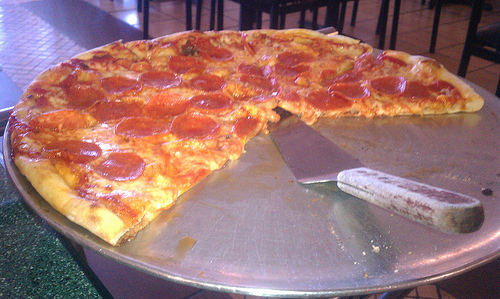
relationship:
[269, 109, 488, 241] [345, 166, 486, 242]
spatula with wooden handle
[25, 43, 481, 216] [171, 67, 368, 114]
pizza has pepperonis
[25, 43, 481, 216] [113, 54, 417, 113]
pizza covered with cheese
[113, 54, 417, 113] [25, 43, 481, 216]
cheese on pizza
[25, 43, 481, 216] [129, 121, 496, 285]
pizza on servingtray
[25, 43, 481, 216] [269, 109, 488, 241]
pizza with spatula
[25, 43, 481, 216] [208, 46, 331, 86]
pizza has redtoppings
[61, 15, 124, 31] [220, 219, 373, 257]
shadow on surface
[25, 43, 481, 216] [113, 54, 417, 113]
pizza made of cheese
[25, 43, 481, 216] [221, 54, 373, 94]
pizza has pepperoni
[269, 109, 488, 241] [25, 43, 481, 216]
spatula serves pizza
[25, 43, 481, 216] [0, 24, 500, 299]
pizza on pizzatray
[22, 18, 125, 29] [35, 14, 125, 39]
floor has tiles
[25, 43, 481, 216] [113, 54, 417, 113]
pizza has cheese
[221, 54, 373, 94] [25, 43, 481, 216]
pepperoni on pizza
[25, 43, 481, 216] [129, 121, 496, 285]
pizza on alluminiumtray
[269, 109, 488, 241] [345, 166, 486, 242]
spatula with woodhandle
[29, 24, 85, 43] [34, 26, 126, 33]
walkway has bricks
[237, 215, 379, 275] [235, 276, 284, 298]
pan reflecting light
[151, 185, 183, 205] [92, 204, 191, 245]
cheese on edge of crust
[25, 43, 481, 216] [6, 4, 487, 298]
pizza in restaraunt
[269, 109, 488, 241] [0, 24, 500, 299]
spatula on pizzatray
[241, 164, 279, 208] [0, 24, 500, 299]
pizzagrease on pizzatray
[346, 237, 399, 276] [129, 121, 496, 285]
crumbs on silvertray